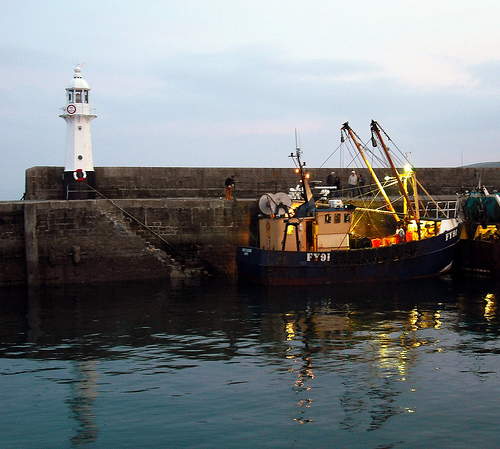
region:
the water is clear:
[224, 402, 253, 446]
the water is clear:
[274, 424, 288, 446]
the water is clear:
[247, 396, 267, 428]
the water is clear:
[239, 391, 253, 416]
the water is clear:
[229, 394, 237, 410]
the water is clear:
[219, 398, 239, 430]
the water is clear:
[245, 415, 259, 437]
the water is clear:
[253, 405, 274, 434]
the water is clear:
[236, 408, 266, 443]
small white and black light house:
[41, 62, 108, 207]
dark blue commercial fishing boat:
[235, 116, 466, 300]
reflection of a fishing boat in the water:
[247, 270, 459, 432]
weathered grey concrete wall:
[2, 157, 499, 295]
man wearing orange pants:
[216, 168, 238, 200]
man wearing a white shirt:
[345, 169, 360, 194]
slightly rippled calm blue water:
[4, 264, 499, 446]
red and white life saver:
[73, 163, 86, 183]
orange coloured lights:
[288, 160, 312, 185]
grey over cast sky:
[1, 0, 498, 202]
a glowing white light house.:
[54, 60, 104, 205]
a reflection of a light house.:
[57, 347, 119, 445]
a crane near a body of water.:
[317, 110, 412, 243]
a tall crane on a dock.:
[270, 120, 321, 263]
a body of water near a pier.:
[0, 276, 498, 445]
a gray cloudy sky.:
[1, 0, 498, 203]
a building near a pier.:
[250, 193, 397, 255]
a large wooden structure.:
[4, 200, 255, 275]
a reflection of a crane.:
[292, 346, 329, 447]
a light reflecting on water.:
[412, 294, 429, 342]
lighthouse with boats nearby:
[50, 71, 495, 423]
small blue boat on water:
[194, 95, 489, 290]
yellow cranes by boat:
[314, 71, 455, 193]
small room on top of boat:
[232, 171, 346, 253]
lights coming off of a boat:
[321, 188, 413, 252]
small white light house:
[31, 54, 122, 192]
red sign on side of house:
[48, 95, 86, 127]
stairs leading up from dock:
[17, 164, 185, 282]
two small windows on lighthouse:
[71, 115, 89, 169]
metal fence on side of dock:
[14, 164, 254, 205]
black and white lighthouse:
[56, 66, 106, 208]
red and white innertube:
[72, 166, 87, 183]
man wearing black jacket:
[222, 176, 237, 196]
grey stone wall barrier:
[26, 166, 499, 294]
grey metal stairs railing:
[68, 186, 208, 280]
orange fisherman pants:
[224, 186, 234, 201]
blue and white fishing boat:
[234, 223, 466, 302]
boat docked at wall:
[243, 121, 460, 297]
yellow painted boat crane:
[338, 121, 423, 232]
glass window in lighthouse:
[73, 87, 82, 104]